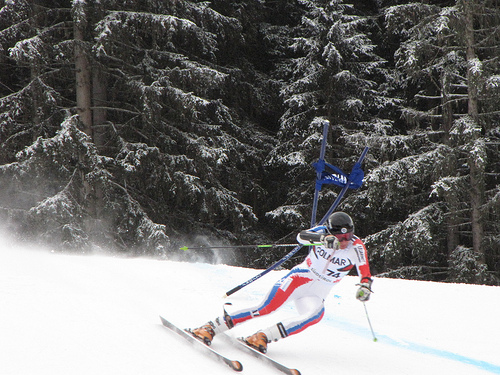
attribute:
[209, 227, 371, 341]
outfit — red, white, blue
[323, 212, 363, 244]
helmet — black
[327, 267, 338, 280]
number — black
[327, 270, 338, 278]
text — black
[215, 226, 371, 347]
clothing — blue, white, red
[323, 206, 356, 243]
helmet — shiny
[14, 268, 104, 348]
snow — white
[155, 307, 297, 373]
skis — silver 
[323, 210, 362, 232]
helmet — black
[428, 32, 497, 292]
trunk — douglas fir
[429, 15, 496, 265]
right — far